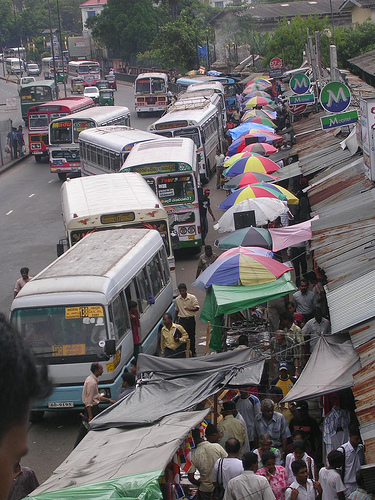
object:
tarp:
[199, 271, 298, 352]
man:
[160, 312, 189, 358]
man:
[172, 282, 200, 358]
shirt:
[285, 413, 323, 457]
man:
[254, 398, 292, 464]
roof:
[307, 151, 373, 249]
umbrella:
[191, 253, 295, 291]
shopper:
[283, 458, 323, 500]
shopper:
[223, 451, 276, 500]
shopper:
[317, 449, 347, 500]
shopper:
[187, 426, 228, 500]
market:
[193, 74, 371, 497]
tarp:
[23, 345, 272, 500]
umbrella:
[222, 154, 282, 179]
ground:
[0, 60, 65, 319]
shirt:
[199, 195, 210, 215]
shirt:
[174, 293, 200, 318]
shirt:
[214, 154, 225, 168]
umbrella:
[217, 185, 286, 211]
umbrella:
[241, 141, 277, 155]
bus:
[8, 228, 175, 421]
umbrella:
[214, 245, 273, 263]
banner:
[197, 43, 208, 59]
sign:
[100, 212, 135, 225]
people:
[291, 279, 318, 321]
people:
[214, 149, 225, 189]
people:
[285, 401, 322, 461]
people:
[72, 362, 117, 449]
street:
[0, 61, 373, 499]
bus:
[48, 105, 130, 181]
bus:
[134, 72, 169, 118]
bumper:
[28, 383, 116, 410]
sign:
[268, 57, 283, 78]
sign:
[289, 73, 318, 107]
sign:
[319, 80, 359, 131]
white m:
[293, 77, 308, 90]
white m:
[326, 87, 349, 108]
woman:
[256, 451, 288, 499]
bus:
[56, 171, 180, 304]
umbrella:
[235, 180, 301, 205]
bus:
[27, 96, 94, 162]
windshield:
[10, 303, 108, 360]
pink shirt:
[255, 464, 291, 499]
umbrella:
[224, 172, 280, 189]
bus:
[118, 137, 203, 254]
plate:
[48, 402, 74, 408]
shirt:
[160, 322, 189, 355]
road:
[5, 164, 54, 230]